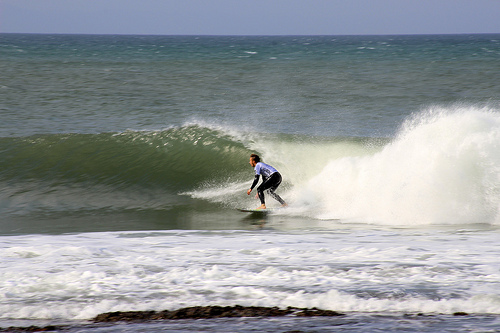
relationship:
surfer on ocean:
[245, 154, 290, 213] [1, 1, 497, 307]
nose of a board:
[237, 206, 254, 214] [238, 206, 287, 214]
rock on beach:
[93, 305, 296, 323] [1, 307, 498, 332]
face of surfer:
[247, 157, 254, 168] [245, 154, 290, 213]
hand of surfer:
[244, 188, 254, 195] [245, 154, 290, 213]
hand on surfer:
[244, 188, 254, 195] [245, 154, 290, 213]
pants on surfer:
[257, 172, 287, 205] [245, 154, 290, 213]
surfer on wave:
[245, 154, 290, 213] [2, 121, 498, 215]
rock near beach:
[93, 305, 296, 323] [1, 307, 498, 332]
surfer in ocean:
[245, 154, 290, 213] [1, 1, 497, 307]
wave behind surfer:
[2, 121, 498, 215] [245, 154, 290, 213]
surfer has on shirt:
[245, 154, 290, 213] [247, 163, 278, 188]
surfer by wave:
[245, 154, 290, 213] [2, 121, 498, 215]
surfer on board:
[245, 154, 290, 213] [238, 206, 287, 214]